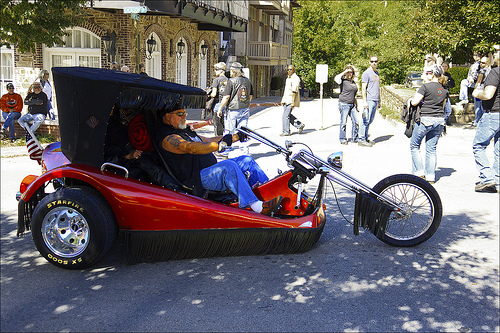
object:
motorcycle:
[12, 115, 452, 267]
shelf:
[49, 64, 207, 158]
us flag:
[24, 119, 45, 159]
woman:
[407, 66, 450, 183]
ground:
[353, 143, 403, 173]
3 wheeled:
[28, 173, 444, 272]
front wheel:
[364, 172, 445, 247]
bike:
[16, 66, 442, 269]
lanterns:
[145, 33, 226, 60]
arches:
[145, 24, 213, 91]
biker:
[153, 102, 283, 217]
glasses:
[178, 112, 184, 116]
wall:
[39, 120, 57, 132]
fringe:
[77, 93, 206, 111]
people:
[216, 59, 444, 177]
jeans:
[217, 107, 250, 159]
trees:
[288, 0, 499, 87]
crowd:
[0, 51, 499, 192]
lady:
[405, 64, 450, 183]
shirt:
[417, 82, 448, 123]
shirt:
[340, 77, 355, 107]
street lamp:
[143, 33, 159, 60]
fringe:
[121, 227, 320, 265]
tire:
[30, 183, 113, 273]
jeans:
[200, 152, 268, 209]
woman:
[0, 82, 23, 140]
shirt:
[1, 92, 23, 112]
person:
[470, 39, 500, 191]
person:
[334, 64, 361, 145]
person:
[358, 55, 382, 148]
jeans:
[409, 116, 444, 175]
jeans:
[470, 111, 499, 182]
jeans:
[338, 99, 358, 140]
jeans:
[359, 101, 376, 140]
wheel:
[367, 173, 443, 247]